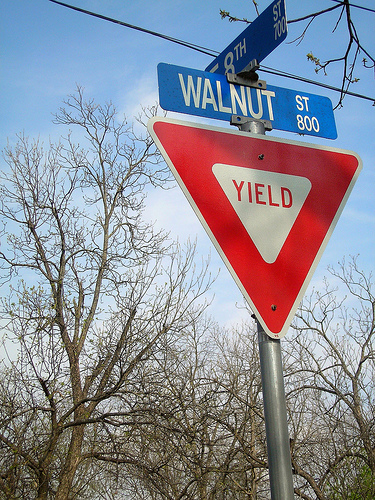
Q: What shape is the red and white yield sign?
A: Triangle.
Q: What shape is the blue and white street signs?
A: Rectangle.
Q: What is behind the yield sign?
A: Trees.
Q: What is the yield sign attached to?
A: A pole.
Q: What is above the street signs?
A: Telephone lines.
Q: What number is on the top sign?
A: 58.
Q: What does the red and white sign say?
A: Yield.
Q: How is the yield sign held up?
A: By a silver pole.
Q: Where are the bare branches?
A: On the trees.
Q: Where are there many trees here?
A: Behind the signs.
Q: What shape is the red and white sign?
A: Triangular.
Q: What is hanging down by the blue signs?
A: A tree branch.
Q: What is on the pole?
A: A yield sign and street signs.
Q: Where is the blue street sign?
A: Above the red sign.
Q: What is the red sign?
A: A yield sign.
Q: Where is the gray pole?
A: Below the signs.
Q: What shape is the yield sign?
A: Triangle.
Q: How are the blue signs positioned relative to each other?
A: Perpendicular.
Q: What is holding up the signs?
A: Metal pole.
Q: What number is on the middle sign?
A: 800.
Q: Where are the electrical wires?
A: Above the top sign.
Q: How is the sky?
A: Blue, sunny, partly cloudy.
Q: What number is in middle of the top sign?
A: 8.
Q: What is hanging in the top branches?
A: Small green buds.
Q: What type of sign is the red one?
A: Yield.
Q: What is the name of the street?
A: Walnut.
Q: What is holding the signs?
A: Pole.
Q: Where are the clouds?
A: Sky.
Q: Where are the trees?
A: Background.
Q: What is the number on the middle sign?
A: 800.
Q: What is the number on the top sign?
A: 700.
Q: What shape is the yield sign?
A: Triangle.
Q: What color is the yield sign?
A: Red and white.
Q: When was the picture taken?
A: Daytime.